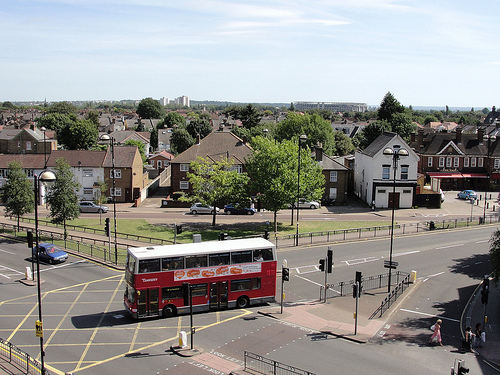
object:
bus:
[123, 237, 276, 321]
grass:
[8, 217, 403, 265]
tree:
[178, 155, 255, 226]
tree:
[242, 134, 327, 236]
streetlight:
[282, 267, 289, 281]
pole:
[280, 264, 285, 314]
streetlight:
[104, 217, 110, 237]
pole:
[104, 218, 113, 262]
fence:
[319, 271, 410, 320]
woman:
[428, 319, 446, 348]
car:
[79, 201, 110, 213]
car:
[32, 243, 68, 265]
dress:
[430, 324, 442, 343]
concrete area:
[257, 280, 421, 342]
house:
[353, 130, 420, 211]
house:
[300, 146, 353, 207]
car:
[190, 203, 221, 215]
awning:
[429, 172, 490, 179]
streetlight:
[182, 282, 191, 306]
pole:
[189, 284, 195, 350]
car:
[286, 197, 319, 209]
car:
[224, 203, 256, 215]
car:
[457, 190, 478, 201]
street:
[1, 206, 500, 373]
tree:
[43, 156, 81, 242]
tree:
[0, 157, 36, 233]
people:
[461, 322, 486, 353]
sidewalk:
[460, 269, 500, 375]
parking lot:
[438, 186, 500, 216]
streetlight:
[327, 250, 334, 274]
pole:
[324, 246, 334, 303]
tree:
[56, 115, 100, 151]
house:
[0, 127, 58, 206]